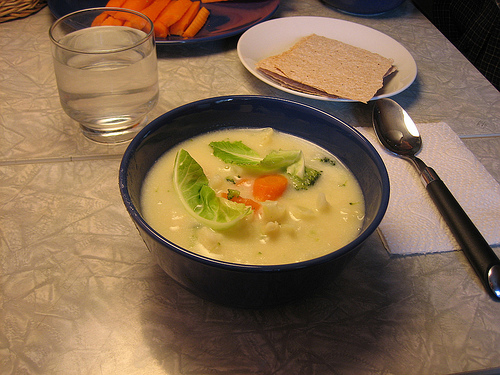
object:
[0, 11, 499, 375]
table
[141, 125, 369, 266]
food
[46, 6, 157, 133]
drink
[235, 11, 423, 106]
saucer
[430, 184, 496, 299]
handle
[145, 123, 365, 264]
soup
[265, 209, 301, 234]
noodles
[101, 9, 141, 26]
glass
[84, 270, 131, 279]
line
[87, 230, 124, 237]
line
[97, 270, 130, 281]
line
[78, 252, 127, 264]
line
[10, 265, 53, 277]
line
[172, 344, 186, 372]
line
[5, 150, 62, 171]
line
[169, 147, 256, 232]
appetizer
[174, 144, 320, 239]
vegetables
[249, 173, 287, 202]
carrots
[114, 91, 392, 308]
plate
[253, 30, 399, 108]
bread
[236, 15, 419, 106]
bowl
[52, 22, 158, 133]
water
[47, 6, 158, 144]
cup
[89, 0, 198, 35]
carrots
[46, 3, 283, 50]
plate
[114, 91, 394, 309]
bowl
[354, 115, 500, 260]
spoon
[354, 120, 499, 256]
napkin